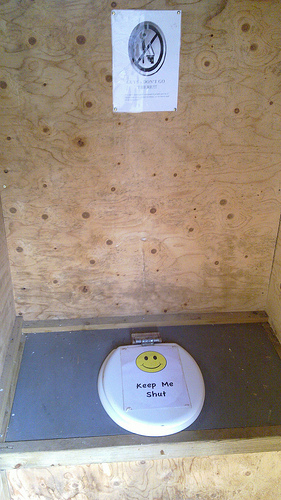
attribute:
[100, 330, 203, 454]
toilet — sink, closed, oval, white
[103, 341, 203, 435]
lid — white, closed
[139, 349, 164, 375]
face — yellow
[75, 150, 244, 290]
wall — wooden, brown, wood grain, swirling, darker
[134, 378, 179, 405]
keep me shut — written, black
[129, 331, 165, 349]
twist — metallic, silver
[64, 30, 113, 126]
cricles — brown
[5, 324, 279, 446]
seat — rectangular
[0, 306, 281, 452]
frame — wooden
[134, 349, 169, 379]
smiley face — yellow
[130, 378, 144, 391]
letter k — black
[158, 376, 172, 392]
letter m — black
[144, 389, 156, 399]
letter s — black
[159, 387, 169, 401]
letter t — black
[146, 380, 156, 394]
letter p — black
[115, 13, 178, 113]
sign — black, white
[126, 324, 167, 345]
hinge — silver